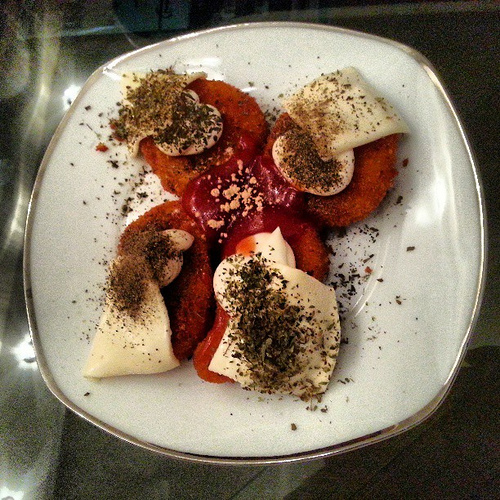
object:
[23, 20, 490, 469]
plate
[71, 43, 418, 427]
food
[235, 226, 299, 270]
cream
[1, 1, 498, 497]
table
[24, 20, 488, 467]
trim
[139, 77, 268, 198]
carrot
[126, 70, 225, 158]
cheese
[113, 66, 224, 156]
spices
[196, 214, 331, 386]
carrot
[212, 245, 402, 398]
spices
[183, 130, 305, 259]
sauce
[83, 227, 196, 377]
cheese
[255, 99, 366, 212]
carrots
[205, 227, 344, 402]
cheese